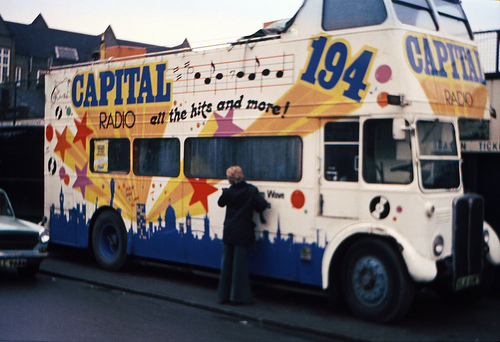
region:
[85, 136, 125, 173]
Small window on a bus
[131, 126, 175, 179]
Small window on a bus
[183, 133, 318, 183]
Small window on a bus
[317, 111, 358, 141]
Small window on a bus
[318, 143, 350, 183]
Small window on a bus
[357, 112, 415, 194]
Small window on a bus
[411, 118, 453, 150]
Small window on a bus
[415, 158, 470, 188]
Small window on a bus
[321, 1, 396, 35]
Small window on a bus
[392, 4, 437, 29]
Small window on a bus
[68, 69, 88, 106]
Blue lettering on a van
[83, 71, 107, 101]
Blue lettering on a van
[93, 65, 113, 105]
Blue lettering on a van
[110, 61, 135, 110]
Blue lettering on a van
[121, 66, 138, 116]
Blue lettering on a van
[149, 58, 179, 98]
Blue lettering on a van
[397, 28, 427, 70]
Blue lettering on a van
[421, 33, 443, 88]
Blue lettering on a van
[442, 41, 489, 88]
Blue lettering on a van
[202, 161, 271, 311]
a person standing on the side of a truck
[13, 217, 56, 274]
left headlight on a vehicle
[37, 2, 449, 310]
radio ad on the side of a truck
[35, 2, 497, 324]
bus with two levels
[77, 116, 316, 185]
windows on the side of a bus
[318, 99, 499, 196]
front windows and the windshield on a truck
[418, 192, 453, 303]
headlights on a white truck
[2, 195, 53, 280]
a car next to the bus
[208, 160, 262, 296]
a person standing next to the bus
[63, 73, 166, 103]
writing on the bus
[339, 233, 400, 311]
a tire on the bus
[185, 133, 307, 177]
a window on the bus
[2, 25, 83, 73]
a building behind the bus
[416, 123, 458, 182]
the windshield on the bus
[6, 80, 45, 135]
a fence behind the bus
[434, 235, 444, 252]
the headlight on the bus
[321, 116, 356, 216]
the door on the bus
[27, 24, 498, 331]
a white bus with colorful design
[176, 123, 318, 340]
a person standing by bus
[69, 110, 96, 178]
a red star on the bus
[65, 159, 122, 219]
a purple star on bus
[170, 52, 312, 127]
music notes on the bus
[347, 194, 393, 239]
a record on the bus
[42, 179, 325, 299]
blue buildings on the bus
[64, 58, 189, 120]
blue letters on the bus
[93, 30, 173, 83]
a brown suitcase on the top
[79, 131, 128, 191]
a sign in the window